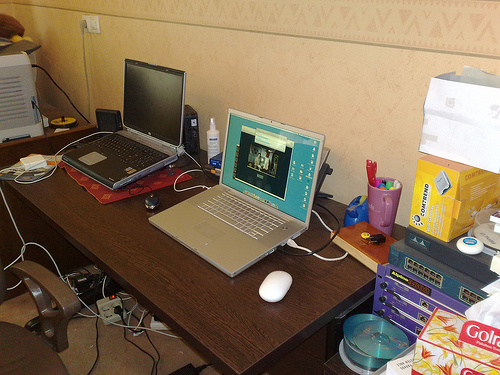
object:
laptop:
[59, 57, 188, 192]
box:
[406, 163, 498, 237]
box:
[388, 228, 500, 308]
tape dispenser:
[342, 194, 368, 227]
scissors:
[362, 155, 382, 184]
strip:
[95, 287, 130, 326]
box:
[414, 65, 499, 175]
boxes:
[349, 262, 499, 374]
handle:
[379, 195, 392, 227]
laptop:
[146, 107, 325, 277]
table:
[6, 146, 409, 372]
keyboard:
[198, 189, 289, 240]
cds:
[350, 319, 412, 360]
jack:
[281, 211, 349, 263]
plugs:
[90, 293, 157, 334]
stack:
[329, 307, 408, 375]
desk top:
[105, 268, 263, 367]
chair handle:
[11, 255, 80, 349]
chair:
[1, 253, 91, 375]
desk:
[0, 114, 353, 375]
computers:
[63, 52, 329, 277]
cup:
[364, 177, 405, 235]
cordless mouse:
[253, 268, 297, 305]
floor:
[67, 319, 166, 368]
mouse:
[142, 195, 161, 214]